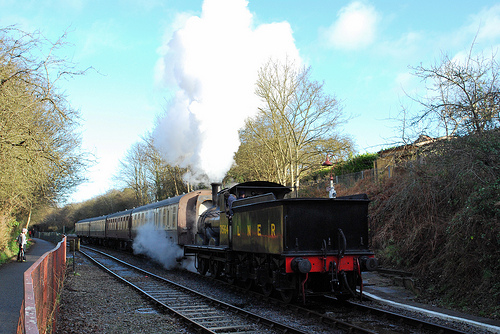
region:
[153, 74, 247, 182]
smoke from a train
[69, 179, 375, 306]
a train on a track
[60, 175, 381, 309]
a moving train on tracks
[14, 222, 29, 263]
a person watching the train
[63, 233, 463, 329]
two tracks that are parallel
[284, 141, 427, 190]
a metal fence behind the train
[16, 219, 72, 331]
a stone wall near the train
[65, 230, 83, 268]
a sign near the tracks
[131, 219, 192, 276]
smoke from the engine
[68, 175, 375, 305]
a train on the tracks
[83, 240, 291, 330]
The railroad track is made of steel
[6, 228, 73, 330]
The wall separating the train tracks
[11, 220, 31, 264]
A person standing on the sidewalk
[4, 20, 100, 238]
The tree is wild with dead leaves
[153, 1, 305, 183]
A cloud of smoke coming from the train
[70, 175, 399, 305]
The train is driving down the tracks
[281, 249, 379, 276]
The front part of the train is red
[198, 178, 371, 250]
The front car on the train is the color black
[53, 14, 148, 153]
The sky is clear and blue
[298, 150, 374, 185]
The edge of the fence has green bushes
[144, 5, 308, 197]
thick white steam coming off the top of the train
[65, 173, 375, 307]
train on the tracks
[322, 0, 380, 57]
small white cloud in the bright blue sky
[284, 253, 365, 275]
red paint on the front of the train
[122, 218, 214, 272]
steam coming out from the bottom of the train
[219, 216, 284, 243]
yellow writing on the ground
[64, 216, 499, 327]
two parallel sets of train tracks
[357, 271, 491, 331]
white line on the ground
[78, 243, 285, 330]
empty set of train tracks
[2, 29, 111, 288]
tree on the side of the train tracks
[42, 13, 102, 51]
white clouds in blue sky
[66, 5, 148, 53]
white clouds in blue sky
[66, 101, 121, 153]
white clouds in blue sky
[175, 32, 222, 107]
white smoke from train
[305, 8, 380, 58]
white clouds in blue sky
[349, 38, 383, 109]
white clouds in blue sky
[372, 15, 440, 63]
white clouds in blue sky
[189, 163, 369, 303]
black train engine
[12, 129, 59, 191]
green leaves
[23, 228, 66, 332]
a red metal railing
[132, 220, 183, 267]
a blast of smoke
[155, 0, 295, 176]
white smoke billowing out of a train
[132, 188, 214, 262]
a traincar on the tracks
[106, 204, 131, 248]
a traincar on the tracks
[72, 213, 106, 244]
train cars on the tracks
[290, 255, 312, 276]
a metal bumper on a train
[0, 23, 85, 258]
trees along a sidewalk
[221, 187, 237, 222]
a man in a train